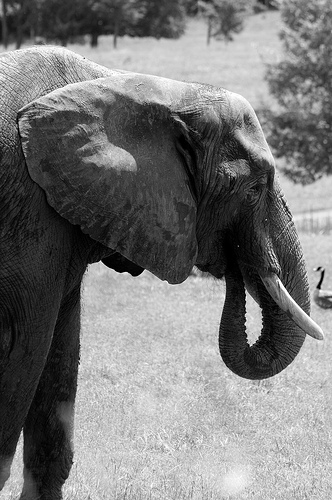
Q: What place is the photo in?
A: It is at the field.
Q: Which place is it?
A: It is a field.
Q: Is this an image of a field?
A: Yes, it is showing a field.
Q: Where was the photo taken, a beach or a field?
A: It was taken at a field.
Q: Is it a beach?
A: No, it is a field.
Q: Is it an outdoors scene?
A: Yes, it is outdoors.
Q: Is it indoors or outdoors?
A: It is outdoors.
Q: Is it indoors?
A: No, it is outdoors.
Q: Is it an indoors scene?
A: No, it is outdoors.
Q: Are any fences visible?
A: No, there are no fences.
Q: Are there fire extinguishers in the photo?
A: No, there are no fire extinguishers.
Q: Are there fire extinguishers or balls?
A: No, there are no fire extinguishers or balls.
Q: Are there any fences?
A: No, there are no fences.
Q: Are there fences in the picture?
A: No, there are no fences.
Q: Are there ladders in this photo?
A: No, there are no ladders.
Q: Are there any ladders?
A: No, there are no ladders.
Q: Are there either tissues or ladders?
A: No, there are no ladders or tissues.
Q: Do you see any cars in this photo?
A: No, there are no cars.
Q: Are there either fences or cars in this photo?
A: No, there are no cars or fences.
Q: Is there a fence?
A: No, there are no fences.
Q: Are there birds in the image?
A: Yes, there is a bird.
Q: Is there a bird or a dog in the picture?
A: Yes, there is a bird.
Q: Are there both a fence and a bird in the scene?
A: No, there is a bird but no fences.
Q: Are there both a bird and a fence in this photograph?
A: No, there is a bird but no fences.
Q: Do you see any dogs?
A: No, there are no dogs.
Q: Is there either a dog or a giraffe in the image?
A: No, there are no dogs or giraffes.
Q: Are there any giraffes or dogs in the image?
A: No, there are no dogs or giraffes.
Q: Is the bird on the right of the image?
A: Yes, the bird is on the right of the image.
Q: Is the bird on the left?
A: No, the bird is on the right of the image.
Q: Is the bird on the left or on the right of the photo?
A: The bird is on the right of the image.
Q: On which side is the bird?
A: The bird is on the right of the image.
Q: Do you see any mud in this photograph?
A: Yes, there is mud.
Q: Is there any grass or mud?
A: Yes, there is mud.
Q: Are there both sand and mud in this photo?
A: No, there is mud but no sand.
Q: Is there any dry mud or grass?
A: Yes, there is dry mud.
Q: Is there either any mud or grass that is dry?
A: Yes, the mud is dry.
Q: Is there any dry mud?
A: Yes, there is dry mud.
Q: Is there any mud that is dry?
A: Yes, there is mud that is dry.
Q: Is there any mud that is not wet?
A: Yes, there is dry mud.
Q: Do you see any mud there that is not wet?
A: Yes, there is dry mud.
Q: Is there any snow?
A: No, there is no snow.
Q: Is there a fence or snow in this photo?
A: No, there are no snow or fences.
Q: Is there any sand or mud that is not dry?
A: No, there is mud but it is dry.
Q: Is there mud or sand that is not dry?
A: No, there is mud but it is dry.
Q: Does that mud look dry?
A: Yes, the mud is dry.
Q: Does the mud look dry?
A: Yes, the mud is dry.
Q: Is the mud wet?
A: No, the mud is dry.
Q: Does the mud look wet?
A: No, the mud is dry.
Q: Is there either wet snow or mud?
A: No, there is mud but it is dry.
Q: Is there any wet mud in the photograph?
A: No, there is mud but it is dry.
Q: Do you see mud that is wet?
A: No, there is mud but it is dry.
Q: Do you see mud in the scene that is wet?
A: No, there is mud but it is dry.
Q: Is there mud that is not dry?
A: No, there is mud but it is dry.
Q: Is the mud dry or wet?
A: The mud is dry.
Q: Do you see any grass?
A: Yes, there is grass.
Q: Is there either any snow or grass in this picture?
A: Yes, there is grass.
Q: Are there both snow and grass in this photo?
A: No, there is grass but no snow.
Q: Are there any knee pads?
A: No, there are no knee pads.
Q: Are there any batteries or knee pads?
A: No, there are no knee pads or batteries.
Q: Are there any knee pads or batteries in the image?
A: No, there are no knee pads or batteries.